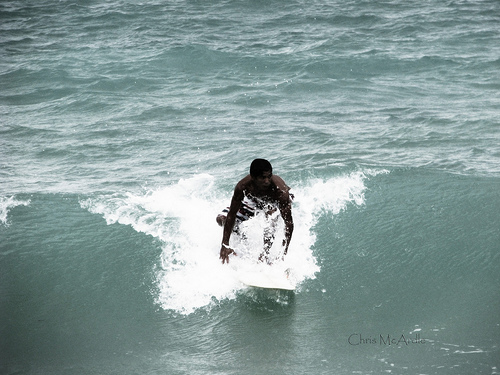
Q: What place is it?
A: It is an ocean.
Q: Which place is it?
A: It is an ocean.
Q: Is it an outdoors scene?
A: Yes, it is outdoors.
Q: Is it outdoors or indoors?
A: It is outdoors.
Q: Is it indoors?
A: No, it is outdoors.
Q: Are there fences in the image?
A: No, there are no fences.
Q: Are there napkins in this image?
A: No, there are no napkins.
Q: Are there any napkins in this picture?
A: No, there are no napkins.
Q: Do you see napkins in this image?
A: No, there are no napkins.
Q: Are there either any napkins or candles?
A: No, there are no napkins or candles.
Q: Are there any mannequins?
A: No, there are no mannequins.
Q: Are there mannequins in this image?
A: No, there are no mannequins.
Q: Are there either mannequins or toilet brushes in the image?
A: No, there are no mannequins or toilet brushes.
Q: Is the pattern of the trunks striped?
A: Yes, the trunks are striped.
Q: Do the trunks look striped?
A: Yes, the trunks are striped.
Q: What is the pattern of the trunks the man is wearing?
A: The trunks are striped.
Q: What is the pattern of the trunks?
A: The trunks are striped.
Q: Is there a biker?
A: No, there are no bikers.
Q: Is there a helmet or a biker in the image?
A: No, there are no bikers or helmets.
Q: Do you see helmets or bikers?
A: No, there are no bikers or helmets.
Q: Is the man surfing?
A: Yes, the man is surfing.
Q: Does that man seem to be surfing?
A: Yes, the man is surfing.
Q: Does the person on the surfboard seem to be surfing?
A: Yes, the man is surfing.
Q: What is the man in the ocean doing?
A: The man is surfing.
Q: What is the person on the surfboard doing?
A: The man is surfing.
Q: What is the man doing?
A: The man is surfing.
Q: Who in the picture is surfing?
A: The man is surfing.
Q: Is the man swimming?
A: No, the man is surfing.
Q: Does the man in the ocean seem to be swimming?
A: No, the man is surfing.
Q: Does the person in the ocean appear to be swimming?
A: No, the man is surfing.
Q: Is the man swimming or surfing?
A: The man is surfing.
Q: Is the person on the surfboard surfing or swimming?
A: The man is surfing.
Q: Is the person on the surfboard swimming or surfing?
A: The man is surfing.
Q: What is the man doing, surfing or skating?
A: The man is surfing.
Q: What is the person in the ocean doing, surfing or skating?
A: The man is surfing.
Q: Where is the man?
A: The man is in the ocean.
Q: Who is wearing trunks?
A: The man is wearing trunks.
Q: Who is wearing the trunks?
A: The man is wearing trunks.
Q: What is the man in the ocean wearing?
A: The man is wearing trunks.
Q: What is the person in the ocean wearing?
A: The man is wearing trunks.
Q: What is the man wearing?
A: The man is wearing trunks.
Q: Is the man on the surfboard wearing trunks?
A: Yes, the man is wearing trunks.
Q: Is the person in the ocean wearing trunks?
A: Yes, the man is wearing trunks.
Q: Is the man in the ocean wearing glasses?
A: No, the man is wearing trunks.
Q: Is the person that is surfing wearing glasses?
A: No, the man is wearing trunks.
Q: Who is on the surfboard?
A: The man is on the surfboard.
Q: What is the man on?
A: The man is on the surf board.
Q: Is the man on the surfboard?
A: Yes, the man is on the surfboard.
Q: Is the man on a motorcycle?
A: No, the man is on the surfboard.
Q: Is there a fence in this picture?
A: No, there are no fences.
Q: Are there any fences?
A: No, there are no fences.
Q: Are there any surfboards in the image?
A: Yes, there is a surfboard.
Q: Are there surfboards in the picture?
A: Yes, there is a surfboard.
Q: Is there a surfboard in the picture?
A: Yes, there is a surfboard.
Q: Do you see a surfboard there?
A: Yes, there is a surfboard.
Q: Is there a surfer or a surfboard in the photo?
A: Yes, there is a surfboard.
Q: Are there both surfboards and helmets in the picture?
A: No, there is a surfboard but no helmets.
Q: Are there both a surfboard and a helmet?
A: No, there is a surfboard but no helmets.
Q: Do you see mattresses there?
A: No, there are no mattresses.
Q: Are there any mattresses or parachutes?
A: No, there are no mattresses or parachutes.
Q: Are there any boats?
A: No, there are no boats.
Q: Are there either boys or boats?
A: No, there are no boats or boys.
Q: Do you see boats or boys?
A: No, there are no boats or boys.